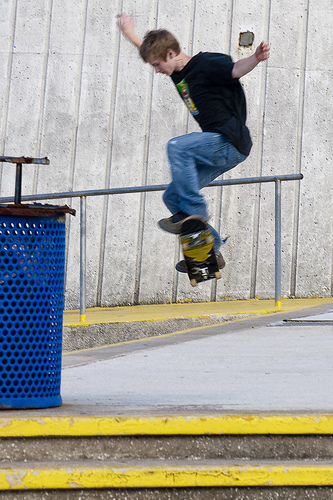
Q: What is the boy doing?
A: Skateboarding.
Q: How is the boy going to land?
A: ON the board.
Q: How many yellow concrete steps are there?
A: Two.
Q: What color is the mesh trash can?
A: Blue.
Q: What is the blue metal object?
A: A trash can.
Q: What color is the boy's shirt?
A: Black.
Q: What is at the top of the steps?
A: A garbage can.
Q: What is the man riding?
A: A skateboard.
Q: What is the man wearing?
A: A shirt and jeans.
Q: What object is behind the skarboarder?
A: A metal rail.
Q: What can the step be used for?
A: Jumps.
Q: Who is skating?
A: One boy.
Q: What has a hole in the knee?
A: The jeans.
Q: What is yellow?
A: The steps.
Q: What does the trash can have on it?
A: Holes.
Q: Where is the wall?
A: Behind the skater.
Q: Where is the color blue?
A: On the handrail.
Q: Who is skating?
A: The boy.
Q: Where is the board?
A: In the air.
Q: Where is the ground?
A: Beneath the boy.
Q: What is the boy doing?
A: Riding a skateboard.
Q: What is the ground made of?
A: Cement.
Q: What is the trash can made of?
A: Metal.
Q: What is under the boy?
A: The skateboard.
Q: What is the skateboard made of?
A: Wood.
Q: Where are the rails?
A: Behind the boy.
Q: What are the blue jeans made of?
A: Denim.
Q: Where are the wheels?
A: Under the skateboard.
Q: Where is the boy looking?
A: At the ground.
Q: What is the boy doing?
A: Skateboarding.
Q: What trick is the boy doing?
A: Jumping.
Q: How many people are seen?
A: 1.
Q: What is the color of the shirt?
A: Black.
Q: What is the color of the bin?
A: Blue.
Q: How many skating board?
A: One.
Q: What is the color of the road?
A: Grey.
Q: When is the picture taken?
A: Daytime.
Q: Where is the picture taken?
A: This photo was taken near a trash can.